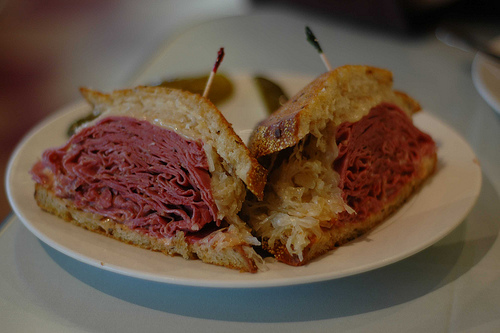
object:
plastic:
[210, 44, 227, 74]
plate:
[4, 68, 484, 289]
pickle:
[248, 73, 292, 113]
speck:
[94, 259, 105, 265]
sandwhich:
[27, 83, 272, 276]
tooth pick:
[200, 46, 227, 98]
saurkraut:
[240, 131, 358, 264]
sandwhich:
[245, 60, 440, 268]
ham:
[23, 114, 235, 247]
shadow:
[36, 169, 498, 324]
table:
[0, 1, 499, 332]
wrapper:
[302, 25, 324, 57]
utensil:
[468, 49, 499, 112]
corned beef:
[24, 115, 232, 248]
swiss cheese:
[73, 91, 208, 142]